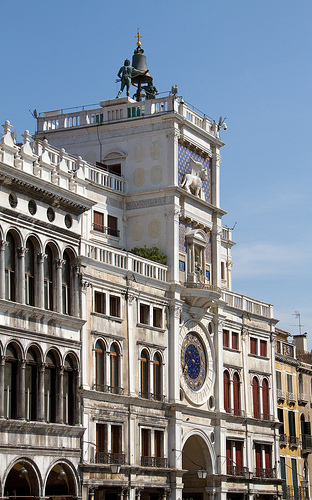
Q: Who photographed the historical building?
A: A tourist.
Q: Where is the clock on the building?
A: Exterior wall.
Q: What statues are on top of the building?
A: Two men.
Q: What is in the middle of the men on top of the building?
A: A bell.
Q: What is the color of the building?
A: White.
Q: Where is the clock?
A: On the wall.